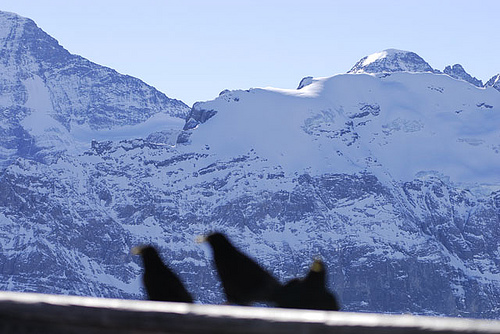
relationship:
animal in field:
[194, 229, 286, 307] [0, 275, 500, 329]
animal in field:
[129, 242, 194, 301] [0, 297, 498, 331]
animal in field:
[282, 261, 339, 310] [1, 10, 499, 317]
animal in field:
[194, 229, 286, 307] [1, 10, 499, 317]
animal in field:
[129, 242, 194, 301] [1, 10, 499, 317]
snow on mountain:
[188, 70, 499, 195] [2, 11, 497, 315]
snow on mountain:
[188, 70, 499, 195] [125, 46, 499, 319]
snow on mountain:
[447, 84, 489, 112] [2, 11, 497, 315]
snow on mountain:
[338, 84, 426, 111] [2, 11, 497, 315]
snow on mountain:
[76, 100, 161, 128] [2, 11, 497, 315]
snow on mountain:
[11, 44, 67, 76] [2, 11, 497, 315]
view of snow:
[417, 91, 486, 154] [425, 97, 487, 179]